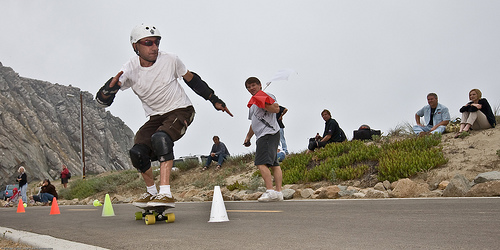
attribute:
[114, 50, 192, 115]
shirt — white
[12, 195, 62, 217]
orange cones — small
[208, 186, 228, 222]
cone — small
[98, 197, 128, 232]
cone — yellow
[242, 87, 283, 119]
flag — orange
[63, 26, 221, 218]
man — skating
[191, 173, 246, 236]
cone — white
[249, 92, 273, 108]
flag — white